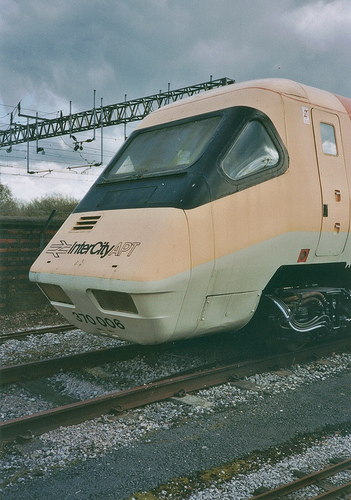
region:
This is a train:
[35, 74, 348, 394]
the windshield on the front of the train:
[106, 112, 227, 178]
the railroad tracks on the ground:
[0, 339, 241, 444]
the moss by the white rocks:
[124, 451, 264, 498]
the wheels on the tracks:
[271, 333, 349, 355]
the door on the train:
[315, 103, 349, 261]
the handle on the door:
[333, 186, 343, 200]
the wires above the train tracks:
[0, 100, 98, 179]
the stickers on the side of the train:
[299, 103, 313, 128]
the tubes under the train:
[277, 290, 328, 308]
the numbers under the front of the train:
[70, 309, 132, 337]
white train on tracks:
[25, 79, 349, 360]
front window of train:
[82, 116, 294, 226]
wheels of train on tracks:
[261, 277, 345, 360]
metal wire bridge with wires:
[40, 85, 117, 145]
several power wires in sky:
[27, 146, 59, 180]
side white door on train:
[303, 109, 349, 256]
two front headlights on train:
[29, 275, 139, 327]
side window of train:
[308, 117, 346, 165]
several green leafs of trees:
[40, 199, 59, 217]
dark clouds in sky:
[69, 5, 117, 50]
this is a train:
[0, 59, 350, 403]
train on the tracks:
[12, 51, 333, 468]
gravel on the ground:
[36, 378, 218, 465]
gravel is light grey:
[36, 374, 188, 462]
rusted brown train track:
[31, 350, 216, 458]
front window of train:
[102, 99, 229, 197]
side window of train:
[220, 119, 275, 198]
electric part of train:
[254, 274, 346, 375]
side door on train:
[305, 98, 350, 257]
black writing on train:
[45, 231, 145, 271]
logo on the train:
[8, 233, 145, 272]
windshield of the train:
[108, 118, 255, 204]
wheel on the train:
[243, 266, 337, 335]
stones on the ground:
[82, 424, 153, 455]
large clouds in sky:
[81, 28, 160, 71]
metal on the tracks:
[22, 353, 84, 407]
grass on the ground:
[183, 458, 219, 485]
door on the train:
[311, 105, 335, 250]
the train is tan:
[209, 225, 251, 251]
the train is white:
[206, 304, 229, 323]